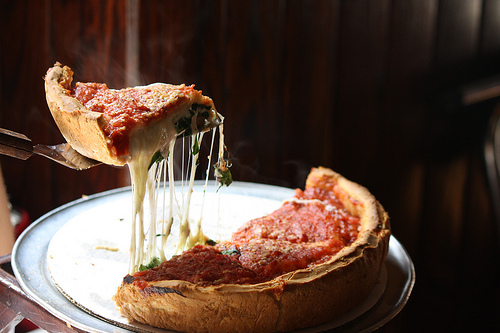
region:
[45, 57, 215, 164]
a slice of pizza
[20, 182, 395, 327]
a white plate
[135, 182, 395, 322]
pizza on a plate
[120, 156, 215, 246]
cheese on the pizza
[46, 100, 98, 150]
the crust of the pizza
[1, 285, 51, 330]
the table under the plate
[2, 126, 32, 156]
the wooden handle of the spatula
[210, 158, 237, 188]
a piece of spinach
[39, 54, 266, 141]
a slice of pizza on top of a spatula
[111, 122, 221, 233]
cheese melting off a pizza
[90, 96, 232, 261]
cheese melting onto a plate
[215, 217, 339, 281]
tomato sauce smothered on a pizza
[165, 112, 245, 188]
spinach oozing out of a pizza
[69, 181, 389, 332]
deep dish pizza sitting on a plate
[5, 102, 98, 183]
a spatula scoping up a pizza slice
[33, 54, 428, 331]
This is food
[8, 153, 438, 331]
This is a white plate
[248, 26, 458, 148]
The table is brown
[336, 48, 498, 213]
A reflection in the table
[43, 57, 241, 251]
Cheese coming off of the food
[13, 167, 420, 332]
Plate is white and blue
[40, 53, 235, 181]
This is red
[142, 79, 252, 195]
Green spinach in the shot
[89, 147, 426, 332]
Half of the food on the plate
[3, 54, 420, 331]
pizza slice is being served to a lucky diner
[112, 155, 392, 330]
a seriously deep dish pan pizza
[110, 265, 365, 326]
the thick crust has been nicely browned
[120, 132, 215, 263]
the cheese is hot and melting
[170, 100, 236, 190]
greens that look like spinach are in this pizza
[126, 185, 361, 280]
tomato sauce heaped on this pizza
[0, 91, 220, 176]
a pizza serving utensil lifting out a slice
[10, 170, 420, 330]
the serving plate is round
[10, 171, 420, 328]
the serving plate is white with gray trim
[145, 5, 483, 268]
a wood paneled wall behind the pizza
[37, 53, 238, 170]
ooy gooey pizza slice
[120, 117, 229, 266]
cheese dripping from slice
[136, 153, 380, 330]
half a pizza pie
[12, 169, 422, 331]
silver plate with pizza on it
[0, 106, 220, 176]
spatula with pizza slice on it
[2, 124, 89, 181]
brown and silver spatula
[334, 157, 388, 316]
golden crust of pizza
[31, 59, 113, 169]
gold crust of pizza slice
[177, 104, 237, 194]
spinach hanging from pizza cheese